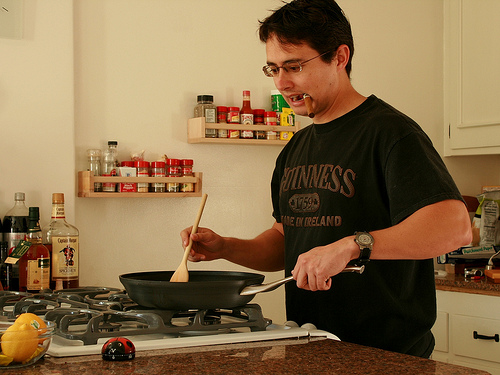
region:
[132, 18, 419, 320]
the man is cooking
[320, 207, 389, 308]
the man is wearing a watch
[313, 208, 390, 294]
the man is wearing a watch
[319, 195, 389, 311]
the man is wearing a watch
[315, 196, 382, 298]
the man is wearing a watch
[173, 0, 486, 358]
A man in the foreground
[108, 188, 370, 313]
Man is holding a frying pan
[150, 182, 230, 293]
Man is holding a wooden spoon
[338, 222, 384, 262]
Man is wearing a wristwatch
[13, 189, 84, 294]
Glass bottles in the background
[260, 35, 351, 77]
Man is wearing eyeglasses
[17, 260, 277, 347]
Pan is on the stove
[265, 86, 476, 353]
Man is wearing a black shirt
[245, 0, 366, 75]
Man has dark colored hair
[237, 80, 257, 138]
Hot sauce in the background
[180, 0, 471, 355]
man is cooking at stove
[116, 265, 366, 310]
large black frying pan with silver handle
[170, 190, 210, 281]
light wooden spoon held by man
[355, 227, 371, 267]
black and silver watch on man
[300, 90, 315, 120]
brown cigar in mans mouth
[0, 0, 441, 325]
white painted wall behind man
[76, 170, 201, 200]
wooden spice rack on wall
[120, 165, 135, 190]
spice container in spice rack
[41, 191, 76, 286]
glass bottle of liquor against wall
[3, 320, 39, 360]
yellow lemon in bowl on counter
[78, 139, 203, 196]
wooden spice rack on wall filled with spices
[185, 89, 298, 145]
wooden spice rack on wall filled with spices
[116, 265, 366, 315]
skillet being used for cooking on a gas range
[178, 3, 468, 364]
man cooking and smoking a cigar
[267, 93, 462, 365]
black Guiness t-shirt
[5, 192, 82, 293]
two bottles of liquor and a bottle of soda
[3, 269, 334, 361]
gas range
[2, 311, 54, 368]
two lemons in a glass bowl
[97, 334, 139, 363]
ladybug shaped kitchen timer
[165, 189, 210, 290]
wooden spoon being used for cooking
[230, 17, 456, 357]
a man with a cigar in his mouth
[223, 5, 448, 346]
a man wearing a dark green shirt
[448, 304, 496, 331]
white cabinets of the kitchen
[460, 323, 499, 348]
black handle of the white cabinet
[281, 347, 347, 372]
brown granite counter top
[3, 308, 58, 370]
a clear glass bowl filled with fruit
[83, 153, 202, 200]
a wood spice rack on the wall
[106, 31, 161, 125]
white wall of the kitchen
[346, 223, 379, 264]
the man's black and grey wrist watch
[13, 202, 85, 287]
two large bottles of liquor on the counter